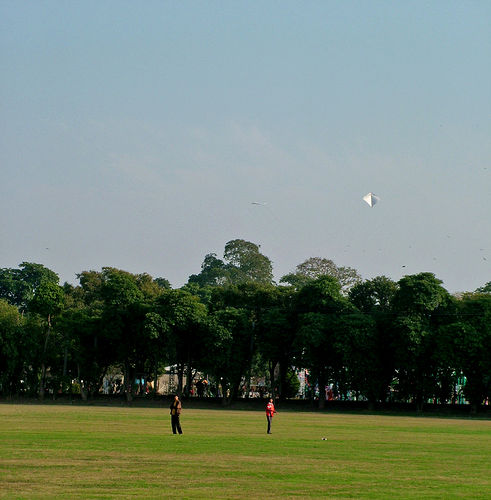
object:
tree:
[48, 275, 142, 402]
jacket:
[170, 399, 182, 414]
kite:
[362, 193, 380, 208]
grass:
[2, 400, 491, 500]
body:
[266, 398, 278, 434]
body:
[170, 395, 183, 434]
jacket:
[266, 402, 275, 417]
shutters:
[458, 377, 465, 385]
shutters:
[457, 396, 464, 405]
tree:
[391, 270, 454, 409]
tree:
[348, 272, 394, 413]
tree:
[287, 273, 366, 401]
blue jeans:
[171, 417, 182, 434]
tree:
[436, 283, 491, 414]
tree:
[0, 260, 61, 394]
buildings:
[157, 351, 470, 405]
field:
[0, 403, 490, 499]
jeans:
[267, 414, 273, 434]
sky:
[0, 3, 488, 294]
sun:
[149, 383, 303, 445]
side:
[2, 349, 486, 414]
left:
[0, 0, 40, 500]